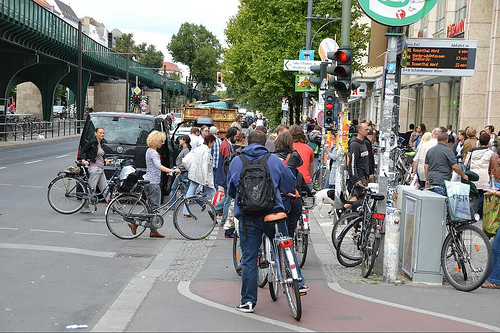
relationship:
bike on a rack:
[338, 192, 381, 278] [366, 186, 382, 276]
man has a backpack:
[426, 133, 468, 196] [236, 153, 274, 217]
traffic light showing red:
[331, 49, 350, 65] [338, 54, 346, 61]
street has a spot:
[0, 139, 499, 333] [91, 218, 114, 224]